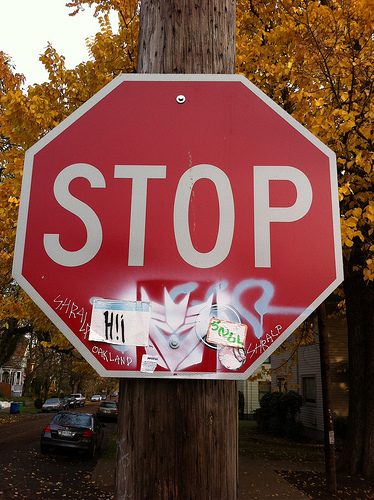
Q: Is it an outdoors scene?
A: Yes, it is outdoors.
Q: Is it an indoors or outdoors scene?
A: It is outdoors.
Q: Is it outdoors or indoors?
A: It is outdoors.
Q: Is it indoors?
A: No, it is outdoors.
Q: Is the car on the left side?
A: Yes, the car is on the left of the image.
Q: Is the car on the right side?
A: No, the car is on the left of the image.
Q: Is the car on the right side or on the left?
A: The car is on the left of the image.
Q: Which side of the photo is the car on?
A: The car is on the left of the image.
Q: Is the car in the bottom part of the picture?
A: Yes, the car is in the bottom of the image.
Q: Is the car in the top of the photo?
A: No, the car is in the bottom of the image.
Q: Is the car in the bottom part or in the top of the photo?
A: The car is in the bottom of the image.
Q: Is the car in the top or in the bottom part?
A: The car is in the bottom of the image.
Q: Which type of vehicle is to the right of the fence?
A: The vehicle is a car.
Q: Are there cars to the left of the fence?
A: No, the car is to the right of the fence.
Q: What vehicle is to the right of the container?
A: The vehicle is a car.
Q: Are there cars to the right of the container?
A: Yes, there is a car to the right of the container.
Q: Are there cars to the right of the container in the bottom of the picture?
A: Yes, there is a car to the right of the container.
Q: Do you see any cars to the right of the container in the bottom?
A: Yes, there is a car to the right of the container.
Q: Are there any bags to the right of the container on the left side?
A: No, there is a car to the right of the container.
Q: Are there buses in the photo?
A: No, there are no buses.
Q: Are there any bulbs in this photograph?
A: No, there are no bulbs.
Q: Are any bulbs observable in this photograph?
A: No, there are no bulbs.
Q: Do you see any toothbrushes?
A: No, there are no toothbrushes.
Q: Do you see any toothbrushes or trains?
A: No, there are no toothbrushes or trains.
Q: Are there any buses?
A: No, there are no buses.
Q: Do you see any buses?
A: No, there are no buses.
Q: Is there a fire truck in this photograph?
A: No, there are no fire trucks.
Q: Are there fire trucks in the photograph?
A: No, there are no fire trucks.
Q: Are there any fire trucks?
A: No, there are no fire trucks.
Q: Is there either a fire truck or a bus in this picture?
A: No, there are no fire trucks or buses.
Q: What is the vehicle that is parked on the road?
A: The vehicle is a car.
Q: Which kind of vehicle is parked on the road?
A: The vehicle is a car.